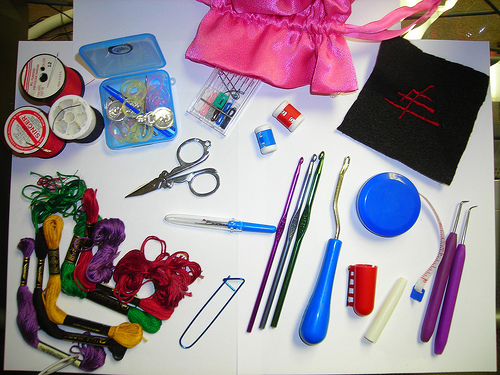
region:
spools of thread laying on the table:
[18, 49, 88, 164]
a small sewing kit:
[188, 60, 253, 142]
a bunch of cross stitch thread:
[18, 167, 150, 362]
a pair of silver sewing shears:
[111, 153, 246, 194]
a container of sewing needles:
[158, 205, 273, 242]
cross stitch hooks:
[450, 192, 479, 353]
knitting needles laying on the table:
[281, 147, 311, 337]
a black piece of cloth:
[343, 32, 479, 182]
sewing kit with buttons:
[96, 77, 188, 152]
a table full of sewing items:
[13, 15, 458, 353]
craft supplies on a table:
[10, 26, 498, 360]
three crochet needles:
[237, 140, 347, 338]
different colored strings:
[1, 204, 156, 359]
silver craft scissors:
[128, 136, 210, 213]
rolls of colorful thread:
[5, 49, 91, 179]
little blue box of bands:
[79, 36, 187, 148]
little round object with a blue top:
[356, 168, 421, 245]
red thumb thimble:
[345, 256, 378, 321]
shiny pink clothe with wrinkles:
[163, 2, 396, 96]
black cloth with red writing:
[331, 41, 479, 139]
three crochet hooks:
[257, 139, 372, 321]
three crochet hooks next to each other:
[215, 124, 322, 359]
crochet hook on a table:
[232, 143, 346, 324]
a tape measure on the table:
[337, 152, 448, 337]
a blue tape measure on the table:
[353, 164, 478, 314]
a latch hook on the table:
[285, 127, 372, 362]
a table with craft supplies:
[19, 20, 496, 373]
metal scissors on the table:
[93, 145, 225, 227]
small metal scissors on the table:
[136, 127, 236, 205]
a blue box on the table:
[69, 25, 203, 155]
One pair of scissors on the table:
[128, 138, 234, 213]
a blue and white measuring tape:
[349, 166, 447, 314]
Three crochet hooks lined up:
[240, 134, 330, 361]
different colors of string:
[3, 166, 213, 370]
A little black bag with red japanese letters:
[336, 22, 486, 176]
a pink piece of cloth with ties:
[181, 1, 439, 97]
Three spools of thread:
[3, 47, 110, 162]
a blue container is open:
[69, 23, 191, 153]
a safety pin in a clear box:
[216, 66, 243, 110]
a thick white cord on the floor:
[28, 5, 78, 36]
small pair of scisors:
[125, 140, 218, 200]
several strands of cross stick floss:
[15, 172, 201, 374]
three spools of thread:
[5, 61, 104, 155]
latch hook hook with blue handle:
[300, 147, 348, 348]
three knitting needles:
[248, 150, 325, 332]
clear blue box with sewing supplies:
[80, 38, 177, 144]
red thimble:
[345, 259, 376, 314]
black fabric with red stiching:
[340, 40, 489, 187]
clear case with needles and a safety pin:
[190, 64, 262, 134]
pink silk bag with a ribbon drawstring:
[184, 2, 441, 92]